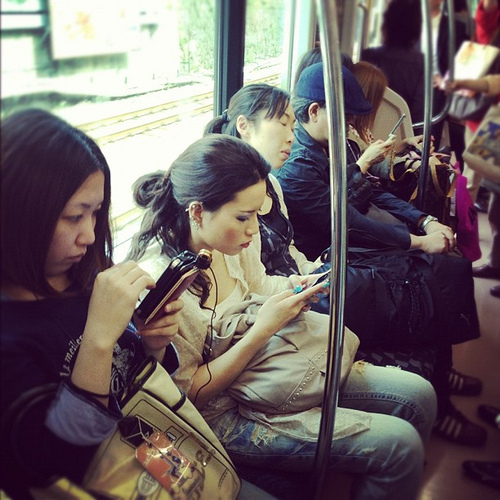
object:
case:
[290, 270, 331, 308]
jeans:
[218, 359, 437, 500]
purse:
[79, 361, 242, 500]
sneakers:
[431, 368, 488, 445]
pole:
[301, 0, 349, 500]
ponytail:
[119, 168, 187, 262]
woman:
[119, 132, 437, 500]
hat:
[293, 61, 374, 118]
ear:
[189, 201, 203, 227]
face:
[205, 179, 267, 256]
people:
[0, 48, 486, 500]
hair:
[0, 107, 117, 301]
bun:
[131, 169, 167, 210]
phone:
[295, 268, 332, 299]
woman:
[204, 82, 436, 376]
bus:
[0, 0, 500, 500]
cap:
[294, 61, 373, 116]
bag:
[206, 292, 360, 416]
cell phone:
[134, 251, 211, 327]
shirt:
[0, 253, 180, 494]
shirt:
[133, 238, 284, 401]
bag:
[405, 161, 451, 225]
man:
[269, 61, 488, 449]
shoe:
[447, 368, 485, 396]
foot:
[444, 367, 486, 398]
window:
[0, 0, 218, 263]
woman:
[0, 107, 277, 499]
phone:
[130, 249, 213, 327]